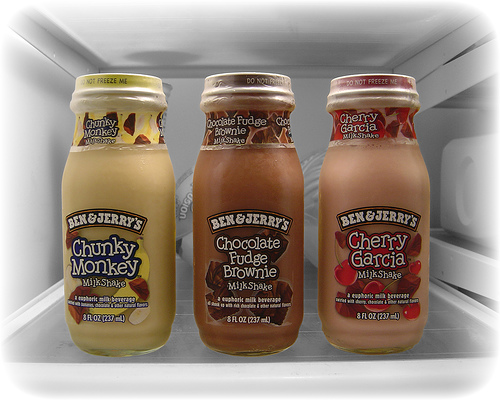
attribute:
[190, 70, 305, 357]
bottle — middle, glass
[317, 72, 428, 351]
bottle — glass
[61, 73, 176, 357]
bottle — glass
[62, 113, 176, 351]
milkshake — flavored, chunky monkey, yellow, 237 ml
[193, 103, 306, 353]
milkshake — chocolate fudge, brown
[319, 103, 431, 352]
milkshake — cherry, pink, cherry garcia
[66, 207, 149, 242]
brand — ben, logo, jerry's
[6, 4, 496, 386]
cooler — white